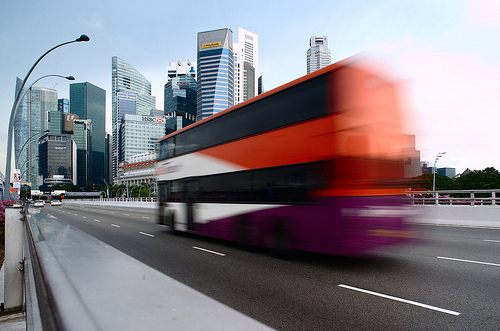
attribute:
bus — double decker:
[127, 36, 442, 311]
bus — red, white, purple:
[145, 63, 422, 281]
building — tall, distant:
[232, 24, 257, 107]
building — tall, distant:
[307, 32, 330, 72]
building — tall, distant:
[107, 52, 151, 191]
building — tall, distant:
[165, 53, 196, 143]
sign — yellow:
[197, 38, 224, 48]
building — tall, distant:
[195, 23, 239, 124]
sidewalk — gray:
[25, 199, 281, 329]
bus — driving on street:
[152, 47, 431, 266]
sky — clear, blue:
[0, 3, 499, 171]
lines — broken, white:
[40, 202, 465, 316]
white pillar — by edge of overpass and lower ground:
[0, 205, 27, 315]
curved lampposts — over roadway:
[0, 25, 93, 200]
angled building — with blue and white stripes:
[192, 27, 238, 117]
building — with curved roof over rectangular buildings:
[107, 50, 163, 162]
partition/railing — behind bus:
[419, 186, 483, 208]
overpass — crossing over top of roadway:
[27, 185, 105, 200]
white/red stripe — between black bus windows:
[153, 119, 347, 181]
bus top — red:
[130, 53, 387, 164]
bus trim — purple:
[218, 203, 408, 253]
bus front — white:
[158, 149, 208, 239]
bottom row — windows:
[160, 159, 335, 208]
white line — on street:
[328, 275, 469, 319]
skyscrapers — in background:
[4, 24, 244, 193]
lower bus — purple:
[203, 193, 410, 253]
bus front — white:
[152, 137, 216, 235]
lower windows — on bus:
[157, 160, 322, 211]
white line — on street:
[189, 240, 228, 258]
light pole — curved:
[2, 30, 92, 208]